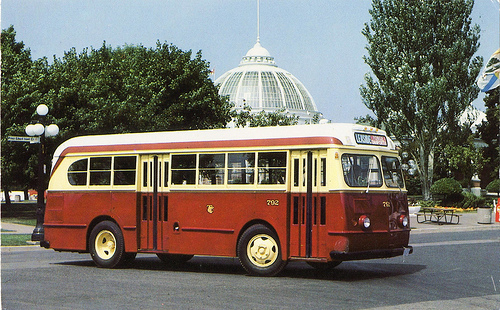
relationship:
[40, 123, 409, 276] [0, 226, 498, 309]
bus on street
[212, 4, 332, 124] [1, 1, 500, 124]
dome in background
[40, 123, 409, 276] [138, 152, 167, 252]
bus has door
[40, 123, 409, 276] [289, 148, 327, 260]
bus has door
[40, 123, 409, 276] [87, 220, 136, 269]
bus has tire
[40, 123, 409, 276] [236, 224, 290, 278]
bus has front tire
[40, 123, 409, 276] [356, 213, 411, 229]
bus has headlights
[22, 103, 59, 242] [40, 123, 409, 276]
lamp behind bus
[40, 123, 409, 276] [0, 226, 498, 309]
bus on road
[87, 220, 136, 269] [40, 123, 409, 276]
tire on bus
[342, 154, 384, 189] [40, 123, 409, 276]
window in bus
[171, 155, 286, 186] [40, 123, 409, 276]
window on bus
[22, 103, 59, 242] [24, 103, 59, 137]
lamp has lights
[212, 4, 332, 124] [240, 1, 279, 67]
building has top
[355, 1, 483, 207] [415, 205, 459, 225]
tree behind table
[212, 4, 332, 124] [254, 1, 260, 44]
building has rod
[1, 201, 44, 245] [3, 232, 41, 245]
walkway has grass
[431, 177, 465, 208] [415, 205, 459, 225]
bush behind table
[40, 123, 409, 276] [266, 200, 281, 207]
bus has number